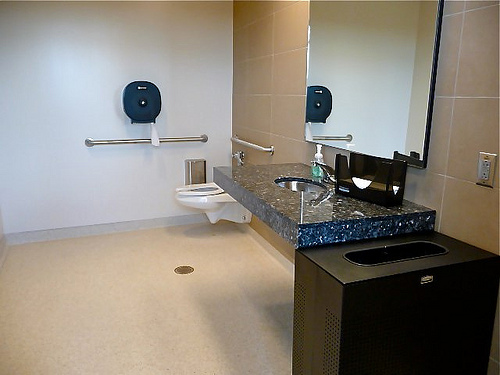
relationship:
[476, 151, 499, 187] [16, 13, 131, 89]
electrical outlet on wall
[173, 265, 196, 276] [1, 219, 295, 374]
drain on floor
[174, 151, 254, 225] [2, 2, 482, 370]
commode in bathroom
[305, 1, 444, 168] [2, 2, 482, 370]
mirror in bathroom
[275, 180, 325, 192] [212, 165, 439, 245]
silver sink in granite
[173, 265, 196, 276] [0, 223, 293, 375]
drain on floor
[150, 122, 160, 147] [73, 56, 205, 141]
paper on wall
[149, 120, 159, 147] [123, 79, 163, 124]
paper out of holder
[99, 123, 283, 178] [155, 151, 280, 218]
bar on commode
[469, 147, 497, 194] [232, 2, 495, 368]
electrical outlet mounted on wall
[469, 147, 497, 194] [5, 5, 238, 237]
electrical outlet mounted on wall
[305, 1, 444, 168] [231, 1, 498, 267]
mirror mounted on wall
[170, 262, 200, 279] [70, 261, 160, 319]
drain on floor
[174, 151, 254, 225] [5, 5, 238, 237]
commode mounted on wall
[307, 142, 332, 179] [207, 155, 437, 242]
bottle on counter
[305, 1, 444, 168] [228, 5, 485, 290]
mirror on wall